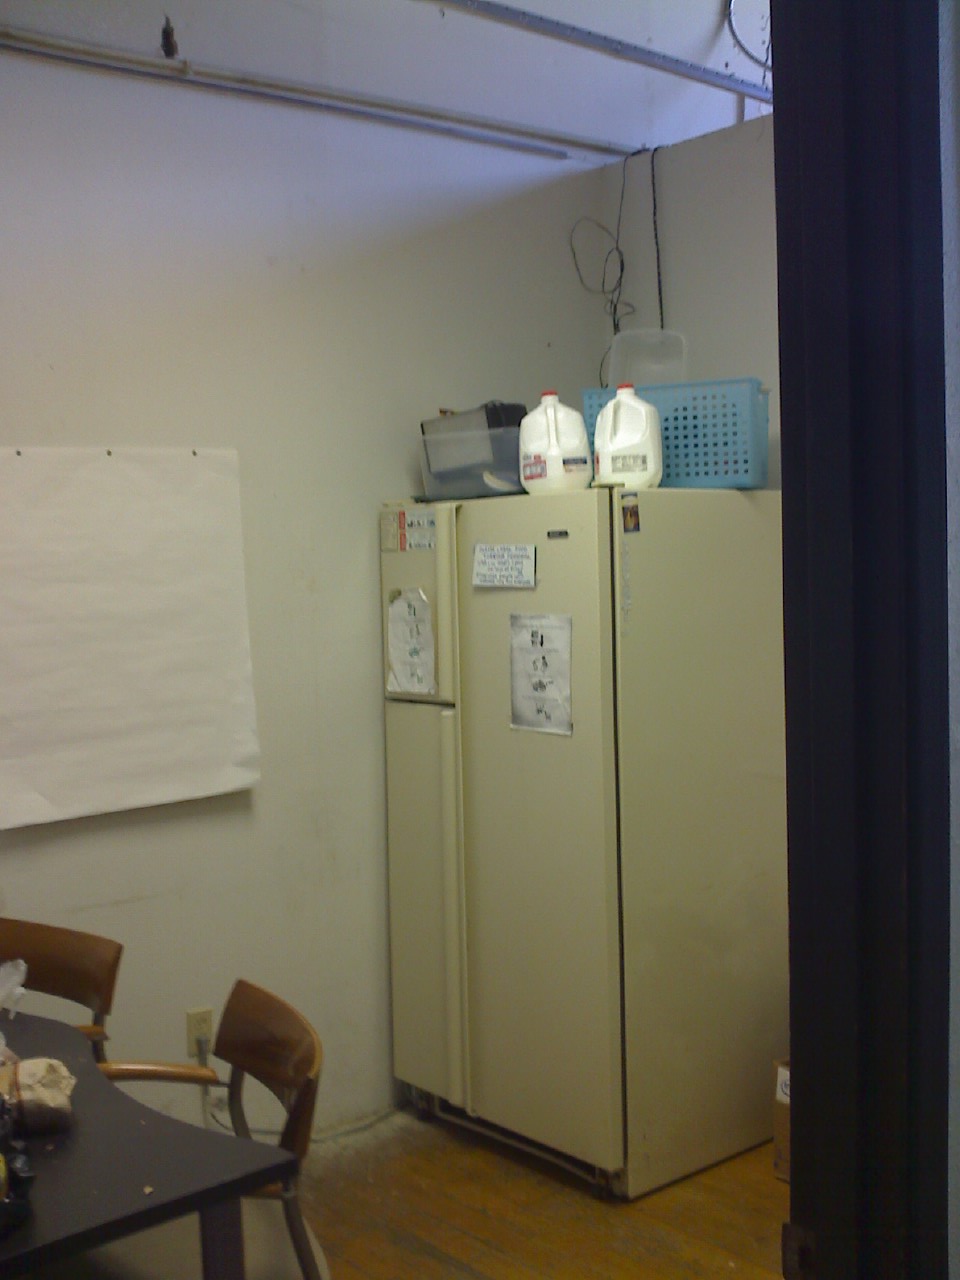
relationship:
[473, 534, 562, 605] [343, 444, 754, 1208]
paper on fridge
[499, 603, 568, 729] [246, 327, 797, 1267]
paper on fridge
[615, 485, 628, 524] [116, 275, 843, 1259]
paper on fridge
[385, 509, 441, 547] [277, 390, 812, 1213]
paper on fridge